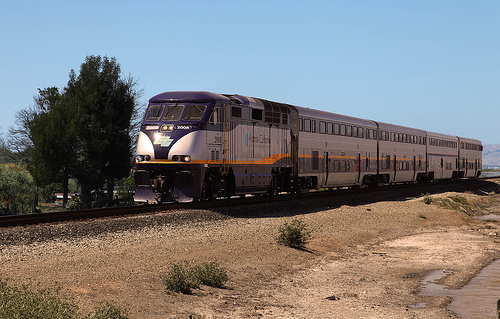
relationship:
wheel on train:
[295, 186, 309, 194] [133, 91, 482, 203]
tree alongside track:
[96, 57, 140, 203] [1, 175, 500, 227]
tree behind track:
[64, 53, 115, 207] [1, 175, 500, 227]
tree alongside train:
[9, 110, 60, 188] [133, 91, 482, 203]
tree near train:
[1, 164, 39, 210] [133, 91, 482, 203]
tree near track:
[96, 57, 140, 203] [1, 175, 500, 227]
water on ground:
[403, 257, 500, 319] [1, 180, 499, 318]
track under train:
[1, 175, 500, 227] [133, 91, 482, 203]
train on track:
[133, 91, 482, 203] [1, 175, 500, 227]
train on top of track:
[133, 91, 482, 203] [1, 175, 500, 227]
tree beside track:
[64, 53, 115, 207] [1, 175, 500, 227]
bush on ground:
[280, 216, 316, 248] [1, 180, 499, 318]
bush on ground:
[193, 264, 229, 288] [1, 180, 499, 318]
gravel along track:
[1, 201, 311, 245] [1, 175, 500, 227]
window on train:
[304, 118, 311, 131] [133, 91, 482, 203]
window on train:
[319, 120, 325, 134] [133, 91, 482, 203]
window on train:
[333, 122, 339, 135] [133, 91, 482, 203]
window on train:
[327, 121, 332, 134] [133, 91, 482, 203]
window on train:
[312, 121, 316, 135] [133, 91, 482, 203]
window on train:
[298, 118, 302, 132] [133, 91, 482, 203]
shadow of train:
[196, 178, 499, 222] [133, 91, 482, 203]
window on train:
[341, 125, 345, 135] [133, 91, 482, 203]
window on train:
[346, 125, 351, 136] [133, 91, 482, 203]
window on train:
[146, 103, 164, 121] [133, 91, 482, 203]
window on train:
[162, 104, 184, 122] [133, 91, 482, 203]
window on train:
[180, 104, 207, 120] [133, 91, 482, 203]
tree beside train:
[96, 57, 140, 203] [133, 91, 482, 203]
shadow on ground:
[196, 178, 499, 222] [1, 180, 499, 318]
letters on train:
[247, 134, 270, 144] [133, 91, 482, 203]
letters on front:
[153, 135, 173, 148] [136, 122, 199, 164]